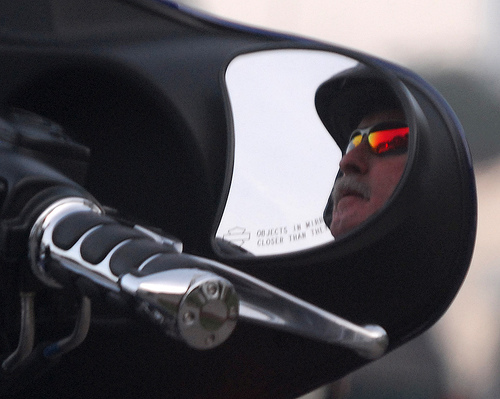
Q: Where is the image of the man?
A: Mirror.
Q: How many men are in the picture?
A: One.